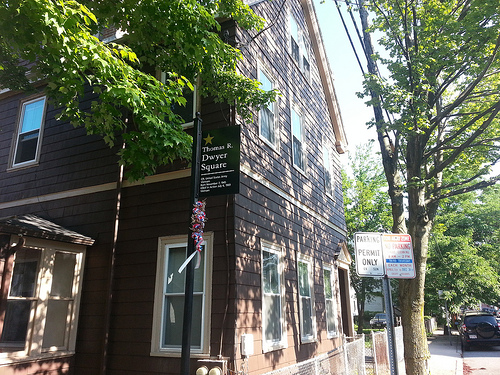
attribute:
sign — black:
[198, 123, 246, 196]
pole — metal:
[180, 106, 203, 374]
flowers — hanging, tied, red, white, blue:
[188, 197, 214, 257]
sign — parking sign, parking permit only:
[347, 227, 389, 279]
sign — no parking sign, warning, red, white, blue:
[381, 228, 417, 283]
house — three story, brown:
[3, 2, 347, 367]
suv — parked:
[458, 307, 497, 352]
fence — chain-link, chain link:
[246, 326, 408, 374]